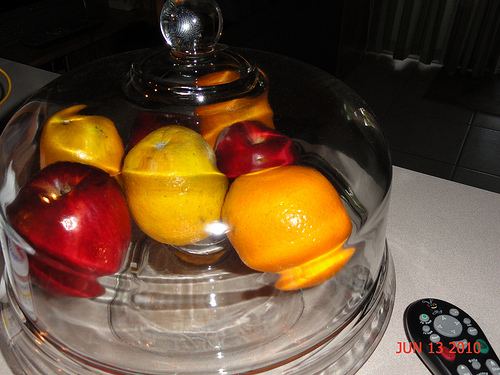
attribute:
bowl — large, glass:
[4, 6, 405, 374]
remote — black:
[399, 292, 499, 374]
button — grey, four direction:
[433, 313, 465, 339]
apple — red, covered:
[208, 120, 299, 174]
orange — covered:
[120, 130, 228, 236]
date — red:
[394, 342, 486, 353]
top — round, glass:
[157, 2, 225, 52]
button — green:
[473, 337, 492, 354]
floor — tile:
[58, 8, 498, 191]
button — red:
[438, 345, 457, 362]